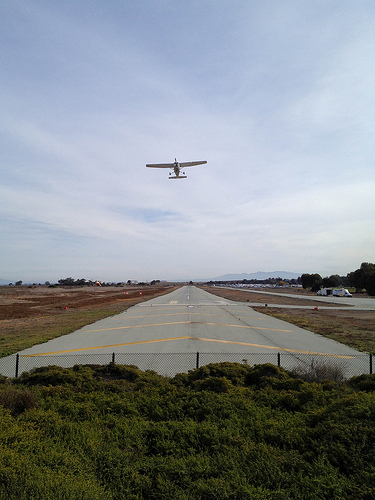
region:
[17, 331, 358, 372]
a yellow line on the runway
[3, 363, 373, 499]
bushes behind the runway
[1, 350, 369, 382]
a fence at the end of the runway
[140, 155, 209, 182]
an airplane in the sky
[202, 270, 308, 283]
a hill is distant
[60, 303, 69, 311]
a pylon near the runway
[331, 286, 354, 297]
a truck on the other runway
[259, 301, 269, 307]
a small sign by the runway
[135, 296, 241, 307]
white lines across the runway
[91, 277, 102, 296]
a windsock by the runway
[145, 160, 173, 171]
the white wing of a plane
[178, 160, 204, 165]
the white wing of a plane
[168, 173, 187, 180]
the white tail of a plane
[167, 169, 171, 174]
the black wheel of the plane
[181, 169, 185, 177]
the black wheel of the plane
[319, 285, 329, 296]
the white truck next to the runway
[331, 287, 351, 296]
the white truck next to the runway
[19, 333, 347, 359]
the yellow painted line on the pavement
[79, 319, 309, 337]
the yellow painted line on the pavement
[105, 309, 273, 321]
the yellow painted line on the pavement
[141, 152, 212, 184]
plane in the sky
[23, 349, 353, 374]
fence by a runway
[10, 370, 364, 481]
green leaves of trees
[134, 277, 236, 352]
runway at an airport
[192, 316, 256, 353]
yellow lines on a runway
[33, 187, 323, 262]
cloudy sky in the distance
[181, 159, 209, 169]
right wing of a plane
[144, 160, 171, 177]
left wing of a plane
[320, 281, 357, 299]
truck on road by runway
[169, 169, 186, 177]
wheels on a plane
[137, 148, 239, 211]
white plane in sky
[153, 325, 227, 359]
yellow paint on road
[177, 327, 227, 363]
gray road on ground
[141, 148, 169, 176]
white paint on plane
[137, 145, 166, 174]
white wing on plane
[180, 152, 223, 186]
white wing on plane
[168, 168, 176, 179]
back wheel on plane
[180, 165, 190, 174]
back wheel on plane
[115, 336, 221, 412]
metal fence by trees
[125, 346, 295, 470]
green trees by fence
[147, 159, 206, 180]
A plane in the sky.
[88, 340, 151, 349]
Part of a yellow line.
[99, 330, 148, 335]
Part of the road.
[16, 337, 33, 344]
Part of the grass.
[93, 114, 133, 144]
Part of the sky.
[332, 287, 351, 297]
A white car in the distance.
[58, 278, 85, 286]
Trees in the distance.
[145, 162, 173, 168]
The left wing of the plane.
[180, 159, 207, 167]
The right wing of the plane.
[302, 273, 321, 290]
A group of green trees.